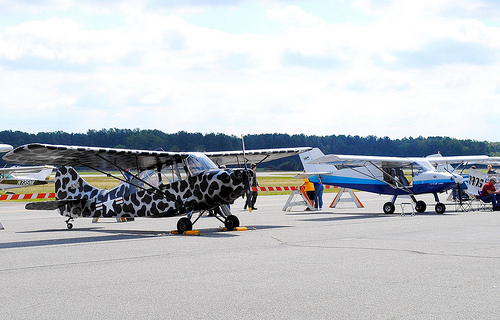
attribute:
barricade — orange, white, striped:
[246, 180, 369, 212]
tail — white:
[301, 149, 336, 177]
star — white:
[101, 194, 117, 212]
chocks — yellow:
[185, 227, 198, 237]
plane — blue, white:
[271, 141, 437, 201]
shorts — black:
[305, 187, 316, 204]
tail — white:
[291, 139, 335, 189]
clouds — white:
[1, 4, 498, 142]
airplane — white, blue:
[293, 145, 488, 212]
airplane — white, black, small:
[110, 102, 224, 219]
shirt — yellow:
[293, 180, 321, 197]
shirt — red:
[452, 174, 482, 205]